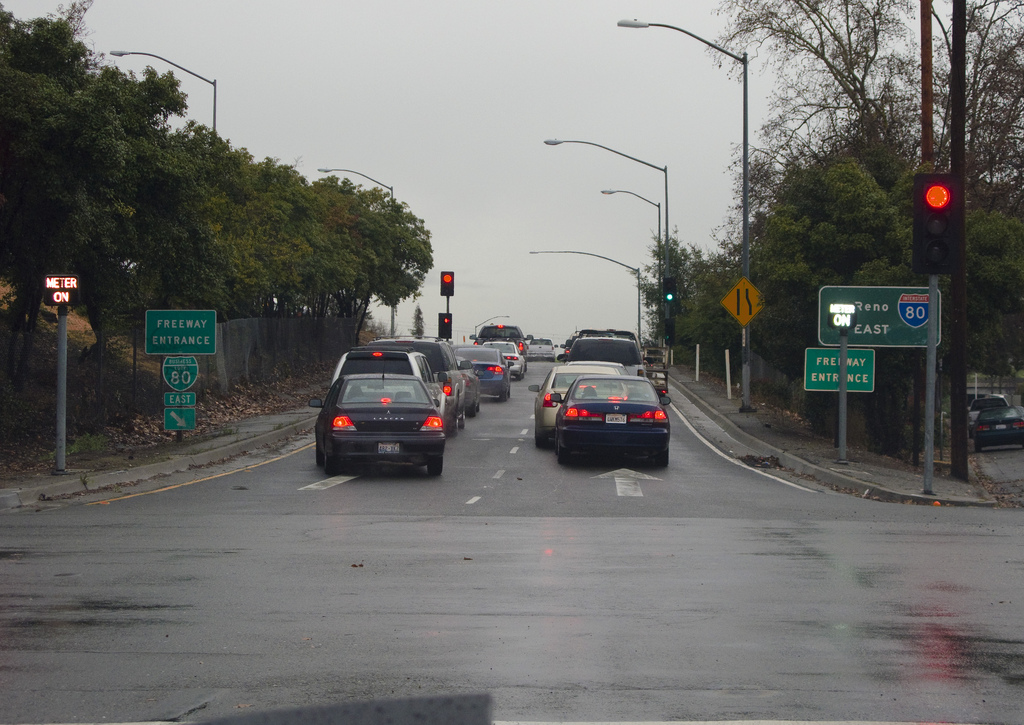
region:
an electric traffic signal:
[912, 166, 967, 278]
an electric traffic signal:
[439, 267, 456, 297]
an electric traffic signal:
[438, 312, 455, 339]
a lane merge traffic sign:
[720, 274, 763, 326]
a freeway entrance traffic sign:
[797, 343, 873, 395]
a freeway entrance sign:
[142, 309, 218, 355]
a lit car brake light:
[565, 405, 588, 419]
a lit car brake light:
[637, 409, 666, 420]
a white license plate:
[604, 413, 628, 424]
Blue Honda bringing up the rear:
[560, 373, 668, 459]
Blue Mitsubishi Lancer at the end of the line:
[315, 370, 446, 468]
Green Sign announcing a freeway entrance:
[143, 309, 219, 433]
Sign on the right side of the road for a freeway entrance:
[801, 351, 875, 389]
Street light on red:
[914, 173, 963, 269]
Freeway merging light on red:
[435, 268, 454, 338]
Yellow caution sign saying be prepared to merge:
[716, 278, 767, 323]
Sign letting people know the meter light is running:
[42, 266, 82, 457]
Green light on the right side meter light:
[661, 275, 677, 317]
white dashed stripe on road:
[460, 410, 537, 508]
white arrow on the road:
[593, 464, 666, 502]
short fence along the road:
[73, 297, 355, 434]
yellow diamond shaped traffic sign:
[718, 275, 766, 330]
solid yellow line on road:
[88, 432, 317, 506]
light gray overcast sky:
[0, 0, 1022, 337]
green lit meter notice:
[824, 297, 862, 463]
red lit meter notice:
[37, 268, 86, 308]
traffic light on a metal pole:
[906, 111, 961, 500]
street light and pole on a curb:
[613, 9, 765, 421]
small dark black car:
[310, 367, 448, 479]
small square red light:
[326, 410, 355, 433]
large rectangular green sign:
[145, 304, 226, 358]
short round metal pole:
[51, 312, 77, 475]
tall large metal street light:
[613, 16, 760, 415]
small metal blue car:
[546, 369, 674, 472]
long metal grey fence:
[203, 306, 362, 399]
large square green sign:
[800, 339, 881, 396]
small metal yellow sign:
[720, 274, 771, 328]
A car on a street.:
[313, 367, 465, 489]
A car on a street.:
[334, 349, 452, 438]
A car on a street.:
[372, 326, 468, 432]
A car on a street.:
[442, 348, 488, 407]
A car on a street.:
[471, 320, 525, 359]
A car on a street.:
[520, 333, 547, 362]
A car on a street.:
[555, 375, 692, 468]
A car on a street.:
[539, 365, 638, 435]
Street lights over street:
[509, 129, 734, 423]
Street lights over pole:
[514, 13, 813, 466]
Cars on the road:
[310, 288, 709, 514]